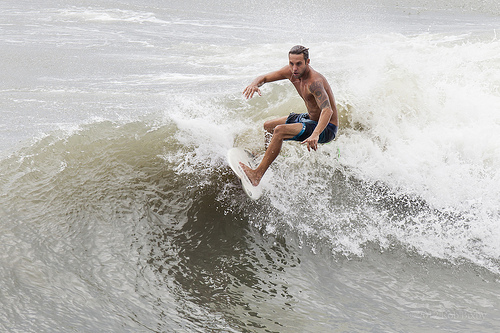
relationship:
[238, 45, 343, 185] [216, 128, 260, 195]
man on surfboard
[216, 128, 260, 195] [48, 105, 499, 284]
surfboard cuts wave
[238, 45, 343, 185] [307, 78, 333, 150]
man has arm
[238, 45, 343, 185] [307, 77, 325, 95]
man has shoulder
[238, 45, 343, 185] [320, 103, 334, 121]
man has elbow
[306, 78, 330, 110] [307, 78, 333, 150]
tattoo on arm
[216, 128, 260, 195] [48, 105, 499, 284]
surfboard on wave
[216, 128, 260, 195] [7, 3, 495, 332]
surfboard in water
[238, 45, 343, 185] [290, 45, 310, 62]
man has hair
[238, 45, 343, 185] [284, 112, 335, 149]
man wears swimsuit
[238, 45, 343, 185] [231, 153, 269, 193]
man has foot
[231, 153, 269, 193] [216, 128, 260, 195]
foot on surfboard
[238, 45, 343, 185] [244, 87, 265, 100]
man has hand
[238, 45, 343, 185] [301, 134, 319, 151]
man has hand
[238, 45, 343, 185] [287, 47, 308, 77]
man has head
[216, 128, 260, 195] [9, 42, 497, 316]
surfboard on wave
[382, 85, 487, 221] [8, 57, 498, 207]
froth created by wave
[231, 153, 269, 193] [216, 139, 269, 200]
foot on surfboard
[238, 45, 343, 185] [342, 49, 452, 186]
man surfing across a wave crest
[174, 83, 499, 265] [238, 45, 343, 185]
wave crest splashing around man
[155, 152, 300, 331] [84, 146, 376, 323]
reflection cast on water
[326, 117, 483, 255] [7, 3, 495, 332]
waves in water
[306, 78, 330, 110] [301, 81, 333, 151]
tattoo on arm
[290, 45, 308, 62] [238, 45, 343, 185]
hair on man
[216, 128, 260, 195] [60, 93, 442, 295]
surfboard in water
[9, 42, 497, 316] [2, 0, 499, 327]
wave in ocean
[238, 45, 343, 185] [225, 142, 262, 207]
man on surfboard